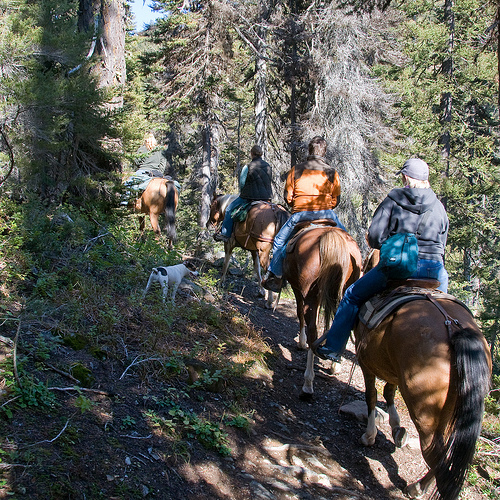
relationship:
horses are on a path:
[127, 182, 480, 455] [160, 232, 402, 499]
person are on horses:
[310, 159, 448, 364] [127, 182, 480, 455]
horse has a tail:
[351, 291, 496, 499] [438, 329, 489, 497]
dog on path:
[137, 246, 207, 308] [160, 232, 402, 499]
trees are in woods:
[3, 2, 141, 249] [1, 3, 500, 496]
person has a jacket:
[260, 135, 349, 294] [283, 161, 345, 220]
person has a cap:
[310, 159, 448, 364] [391, 151, 433, 185]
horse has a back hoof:
[351, 291, 496, 499] [390, 420, 411, 450]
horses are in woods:
[127, 182, 480, 455] [1, 3, 500, 496]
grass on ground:
[28, 203, 253, 412] [1, 200, 495, 498]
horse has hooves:
[351, 291, 496, 499] [356, 402, 410, 455]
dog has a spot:
[137, 246, 207, 308] [154, 263, 172, 279]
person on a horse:
[271, 137, 339, 269] [275, 224, 362, 332]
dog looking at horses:
[137, 246, 207, 308] [127, 182, 480, 455]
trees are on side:
[3, 2, 141, 249] [28, 203, 253, 412]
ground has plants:
[1, 200, 495, 498] [28, 203, 253, 412]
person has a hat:
[310, 159, 448, 364] [391, 151, 433, 185]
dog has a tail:
[137, 246, 207, 308] [144, 269, 162, 298]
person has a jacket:
[271, 137, 339, 269] [283, 161, 345, 220]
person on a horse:
[310, 161, 448, 364] [351, 291, 496, 499]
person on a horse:
[220, 146, 275, 232] [208, 193, 289, 257]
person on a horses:
[139, 132, 164, 179] [119, 177, 179, 247]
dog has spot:
[137, 246, 207, 308] [154, 263, 172, 279]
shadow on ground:
[220, 265, 414, 490] [1, 200, 495, 498]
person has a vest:
[220, 146, 275, 232] [246, 163, 273, 203]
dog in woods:
[137, 246, 207, 308] [1, 3, 500, 496]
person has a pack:
[310, 161, 448, 364] [375, 230, 427, 278]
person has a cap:
[310, 161, 448, 364] [395, 157, 431, 180]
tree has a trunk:
[72, 8, 147, 229] [73, 90, 135, 217]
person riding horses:
[139, 132, 164, 179] [119, 177, 179, 247]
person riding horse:
[220, 146, 275, 232] [208, 193, 289, 257]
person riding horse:
[271, 137, 339, 269] [275, 224, 362, 332]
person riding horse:
[310, 161, 448, 364] [351, 291, 496, 499]